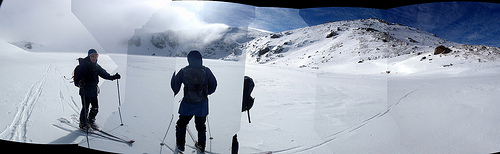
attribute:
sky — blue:
[351, 13, 488, 45]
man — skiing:
[73, 47, 120, 132]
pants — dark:
[81, 94, 99, 127]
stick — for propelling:
[115, 71, 124, 129]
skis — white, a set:
[59, 125, 135, 145]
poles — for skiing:
[111, 71, 126, 123]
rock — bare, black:
[433, 42, 451, 55]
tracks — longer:
[319, 75, 437, 150]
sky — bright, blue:
[362, 3, 496, 18]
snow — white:
[316, 42, 445, 149]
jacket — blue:
[163, 66, 220, 118]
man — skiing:
[170, 48, 219, 152]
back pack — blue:
[223, 74, 270, 124]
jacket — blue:
[173, 64, 217, 113]